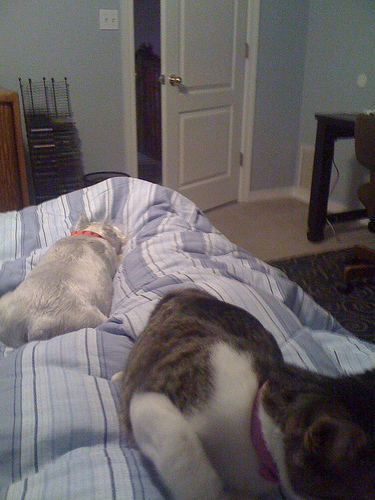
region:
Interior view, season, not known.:
[4, 5, 368, 499]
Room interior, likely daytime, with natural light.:
[6, 3, 372, 498]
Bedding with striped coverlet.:
[0, 177, 372, 491]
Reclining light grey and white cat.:
[7, 201, 117, 348]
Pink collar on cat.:
[68, 222, 106, 250]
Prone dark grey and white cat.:
[140, 288, 368, 499]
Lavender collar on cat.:
[244, 379, 290, 490]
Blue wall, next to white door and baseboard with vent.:
[161, 38, 299, 236]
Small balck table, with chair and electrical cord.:
[308, 99, 374, 245]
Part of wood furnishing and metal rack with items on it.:
[3, 91, 109, 204]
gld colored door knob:
[166, 66, 185, 93]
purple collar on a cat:
[239, 350, 280, 488]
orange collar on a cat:
[68, 221, 108, 247]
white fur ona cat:
[220, 401, 233, 434]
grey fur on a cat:
[52, 257, 81, 292]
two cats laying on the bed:
[19, 208, 355, 498]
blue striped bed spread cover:
[39, 347, 125, 456]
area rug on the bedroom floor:
[273, 234, 336, 288]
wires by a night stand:
[311, 152, 357, 249]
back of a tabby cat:
[151, 309, 201, 368]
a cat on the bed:
[2, 223, 115, 340]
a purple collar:
[249, 428, 271, 456]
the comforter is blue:
[8, 360, 103, 474]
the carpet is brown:
[229, 200, 283, 254]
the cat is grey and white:
[114, 289, 371, 497]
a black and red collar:
[83, 227, 95, 237]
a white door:
[169, 154, 237, 196]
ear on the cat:
[308, 414, 358, 463]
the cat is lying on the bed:
[1, 211, 118, 348]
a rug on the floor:
[287, 258, 324, 277]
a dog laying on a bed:
[0, 209, 129, 345]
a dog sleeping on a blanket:
[0, 208, 132, 347]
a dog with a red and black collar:
[0, 205, 128, 348]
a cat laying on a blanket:
[119, 283, 374, 497]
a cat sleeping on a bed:
[125, 285, 373, 498]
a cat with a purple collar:
[119, 286, 372, 496]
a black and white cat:
[120, 288, 373, 498]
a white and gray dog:
[2, 211, 132, 344]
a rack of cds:
[18, 73, 88, 195]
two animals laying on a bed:
[0, 210, 372, 499]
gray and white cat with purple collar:
[128, 291, 373, 495]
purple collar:
[249, 373, 280, 487]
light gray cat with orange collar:
[8, 223, 121, 339]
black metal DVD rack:
[21, 73, 86, 198]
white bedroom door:
[158, 1, 245, 215]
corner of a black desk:
[303, 106, 373, 243]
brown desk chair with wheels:
[341, 113, 373, 294]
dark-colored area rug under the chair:
[267, 241, 374, 351]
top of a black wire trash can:
[83, 170, 129, 186]